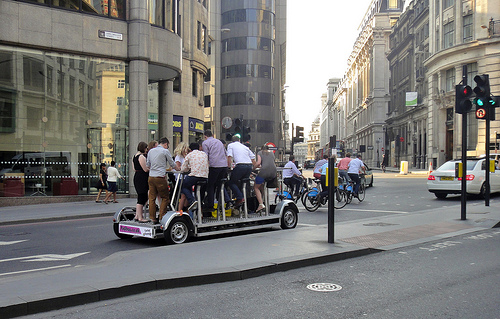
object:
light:
[474, 96, 485, 107]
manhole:
[305, 281, 342, 293]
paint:
[0, 242, 108, 264]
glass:
[62, 88, 102, 125]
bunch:
[341, 151, 371, 205]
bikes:
[346, 153, 368, 202]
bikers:
[282, 156, 309, 201]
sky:
[315, 16, 347, 39]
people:
[131, 135, 181, 226]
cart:
[112, 205, 294, 245]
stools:
[239, 176, 283, 217]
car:
[426, 154, 496, 201]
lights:
[452, 86, 475, 98]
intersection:
[408, 170, 426, 227]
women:
[95, 163, 109, 203]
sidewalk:
[0, 187, 127, 208]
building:
[307, 40, 499, 174]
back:
[376, 10, 389, 27]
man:
[204, 125, 227, 215]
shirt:
[200, 136, 227, 167]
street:
[376, 168, 428, 218]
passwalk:
[109, 243, 221, 283]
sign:
[405, 92, 419, 106]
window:
[222, 63, 243, 79]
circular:
[224, 2, 279, 38]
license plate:
[116, 224, 161, 239]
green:
[476, 98, 487, 106]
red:
[462, 84, 469, 97]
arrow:
[0, 233, 44, 248]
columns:
[366, 29, 389, 125]